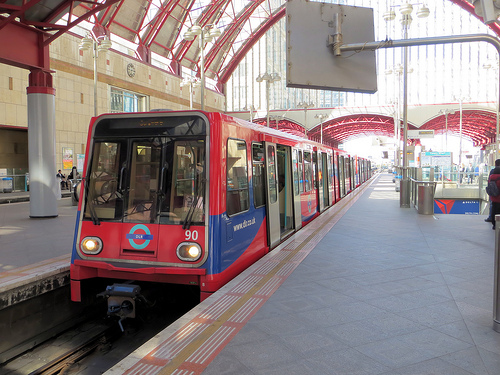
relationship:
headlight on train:
[175, 238, 202, 261] [71, 108, 371, 349]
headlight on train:
[77, 232, 103, 255] [71, 108, 371, 349]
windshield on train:
[82, 115, 207, 222] [71, 108, 371, 349]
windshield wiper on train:
[183, 191, 203, 229] [71, 108, 371, 349]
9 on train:
[183, 222, 197, 246] [71, 108, 371, 349]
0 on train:
[185, 228, 196, 242] [33, 68, 394, 327]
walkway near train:
[174, 161, 495, 371] [71, 108, 371, 349]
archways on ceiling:
[248, 111, 498, 154] [64, 19, 498, 153]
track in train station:
[26, 324, 126, 374] [0, 0, 500, 375]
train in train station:
[69, 107, 379, 333] [0, 0, 500, 368]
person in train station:
[478, 156, 498, 221] [0, 0, 500, 368]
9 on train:
[185, 230, 192, 241] [73, 103, 370, 303]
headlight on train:
[175, 238, 202, 261] [73, 103, 370, 303]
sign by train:
[283, 0, 377, 95] [71, 108, 371, 349]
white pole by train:
[27, 92, 59, 220] [66, 106, 376, 322]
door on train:
[261, 141, 318, 239] [66, 106, 376, 322]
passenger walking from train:
[484, 157, 498, 221] [71, 108, 371, 349]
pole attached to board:
[345, 32, 499, 59] [278, 1, 382, 93]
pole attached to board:
[393, 19, 413, 201] [278, 1, 382, 93]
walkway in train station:
[100, 171, 500, 375] [0, 0, 500, 368]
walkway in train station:
[0, 198, 77, 274] [0, 0, 500, 368]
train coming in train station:
[66, 106, 376, 322] [0, 0, 500, 375]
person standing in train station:
[476, 158, 498, 231] [0, 0, 500, 368]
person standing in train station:
[64, 160, 76, 204] [0, 0, 500, 368]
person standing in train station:
[52, 167, 62, 182] [0, 0, 500, 368]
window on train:
[82, 117, 205, 222] [51, 72, 391, 294]